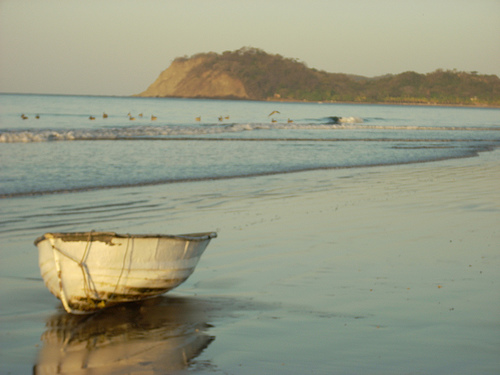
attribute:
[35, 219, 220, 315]
boat — white, old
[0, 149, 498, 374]
shore — wet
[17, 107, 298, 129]
birds — moving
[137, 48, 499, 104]
hills — brown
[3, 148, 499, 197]
coast — green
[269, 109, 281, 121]
seagull — white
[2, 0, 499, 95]
sky — hazy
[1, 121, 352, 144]
waves — crashing